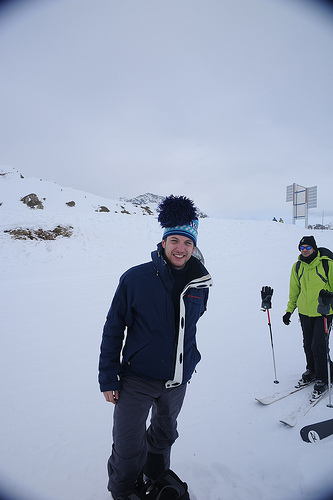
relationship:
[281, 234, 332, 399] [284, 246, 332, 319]
skier wearing jacket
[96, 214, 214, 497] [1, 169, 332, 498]
skier in snow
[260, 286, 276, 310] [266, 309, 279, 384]
glove on top of ski pole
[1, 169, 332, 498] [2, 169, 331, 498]
snow on ground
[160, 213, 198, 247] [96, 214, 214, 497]
hat on skier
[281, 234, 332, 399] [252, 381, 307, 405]
skier wearing ski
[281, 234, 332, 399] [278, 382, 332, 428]
skier wearing ski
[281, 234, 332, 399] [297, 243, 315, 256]
skier has face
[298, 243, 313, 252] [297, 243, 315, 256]
sunglasses on face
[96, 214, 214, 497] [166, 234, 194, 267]
skier has face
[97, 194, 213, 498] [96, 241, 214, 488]
man wearing clothes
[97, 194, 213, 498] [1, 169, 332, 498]
man standing in snow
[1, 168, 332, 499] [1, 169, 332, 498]
hill in snow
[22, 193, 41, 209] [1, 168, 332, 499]
rock on hill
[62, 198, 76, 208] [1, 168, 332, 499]
rock on hill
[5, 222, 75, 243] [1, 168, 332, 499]
bush on hill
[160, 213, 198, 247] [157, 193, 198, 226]
hat has topper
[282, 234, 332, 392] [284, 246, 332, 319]
man wearing jacket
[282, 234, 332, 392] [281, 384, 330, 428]
man wearing ski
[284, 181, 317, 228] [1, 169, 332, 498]
sign in snow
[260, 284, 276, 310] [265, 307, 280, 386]
glove on ski pole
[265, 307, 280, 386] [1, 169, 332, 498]
ski pole in snow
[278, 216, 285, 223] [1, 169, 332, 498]
tree poking out of snow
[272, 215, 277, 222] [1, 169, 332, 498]
tree poking out of snow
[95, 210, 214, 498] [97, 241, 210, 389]
person wearing jacket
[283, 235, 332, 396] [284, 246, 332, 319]
person wearing jacket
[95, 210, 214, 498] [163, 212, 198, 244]
person wearing hat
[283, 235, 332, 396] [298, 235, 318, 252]
person wearing hat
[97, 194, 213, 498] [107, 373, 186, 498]
man wearing pants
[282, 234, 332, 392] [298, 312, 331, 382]
man wearing pants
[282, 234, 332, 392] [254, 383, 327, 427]
man wearing skis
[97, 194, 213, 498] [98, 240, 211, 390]
man wearing ski jacket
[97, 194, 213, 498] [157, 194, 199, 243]
man wearing cap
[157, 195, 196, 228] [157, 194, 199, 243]
ball on cap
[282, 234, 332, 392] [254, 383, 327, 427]
man on skis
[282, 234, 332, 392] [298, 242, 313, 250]
man wearing sunglasses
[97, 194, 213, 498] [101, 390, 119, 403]
man has hand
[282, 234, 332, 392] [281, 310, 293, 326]
man has hand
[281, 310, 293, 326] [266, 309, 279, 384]
hand next to ski pole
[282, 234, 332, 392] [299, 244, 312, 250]
man wearing sunglasses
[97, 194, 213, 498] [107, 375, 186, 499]
man wearing sweatpants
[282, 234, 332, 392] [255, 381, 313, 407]
man wearing ski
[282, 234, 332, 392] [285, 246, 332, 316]
man wearing sweater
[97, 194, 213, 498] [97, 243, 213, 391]
man wearing sweater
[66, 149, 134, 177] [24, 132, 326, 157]
clear overcast sky